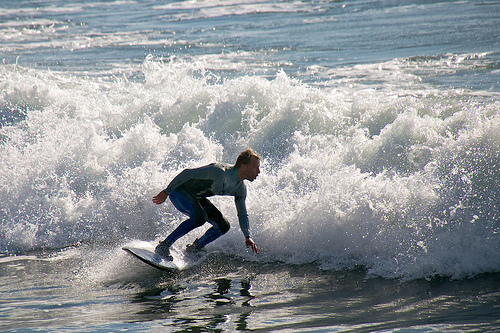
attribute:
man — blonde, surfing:
[152, 149, 262, 263]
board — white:
[120, 245, 210, 274]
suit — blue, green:
[163, 161, 251, 255]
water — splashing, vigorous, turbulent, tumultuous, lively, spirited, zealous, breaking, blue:
[0, 1, 500, 332]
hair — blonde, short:
[235, 148, 261, 172]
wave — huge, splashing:
[1, 57, 500, 293]